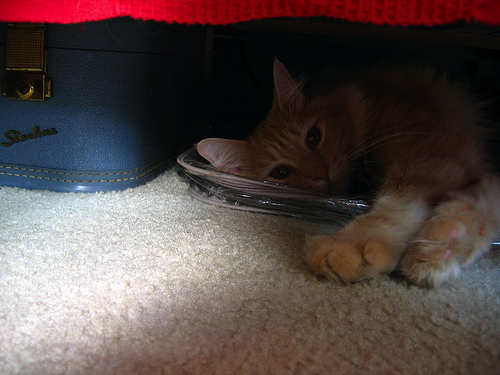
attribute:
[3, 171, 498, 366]
carpet — Synthetic , Beige 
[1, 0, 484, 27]
cloth — red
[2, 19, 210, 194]
luggage — Blue 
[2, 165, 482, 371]
floor — white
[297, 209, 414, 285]
paw — furry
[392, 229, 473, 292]
paw — furry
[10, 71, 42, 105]
buckle — metal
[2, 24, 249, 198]
luggage — blue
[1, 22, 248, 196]
suitcase — large, blue, old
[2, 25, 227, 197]
suitcase — blue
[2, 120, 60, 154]
word — black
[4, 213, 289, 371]
carpet — white